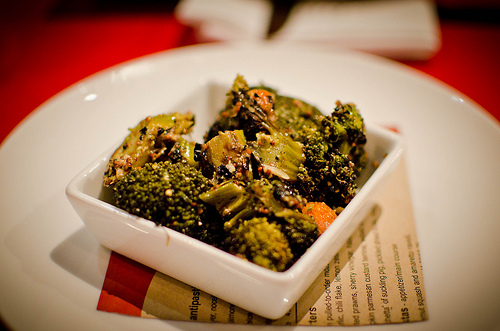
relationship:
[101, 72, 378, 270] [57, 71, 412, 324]
veggie in bowl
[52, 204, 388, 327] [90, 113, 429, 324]
bowl shadow on the paper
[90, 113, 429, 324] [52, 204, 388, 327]
paper under bowl shadow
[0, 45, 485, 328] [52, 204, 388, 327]
plate under bowl shadow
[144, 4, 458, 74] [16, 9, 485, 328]
white towel is on table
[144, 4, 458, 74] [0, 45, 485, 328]
white towel near plate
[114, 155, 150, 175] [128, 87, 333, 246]
spices on vegetables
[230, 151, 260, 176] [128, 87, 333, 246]
spices on vegetables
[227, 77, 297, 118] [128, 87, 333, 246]
spices on vegetables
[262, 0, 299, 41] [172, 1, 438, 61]
knife on towel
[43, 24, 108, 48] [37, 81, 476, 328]
table cloth underneath plate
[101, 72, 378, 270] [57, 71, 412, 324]
veggie in a bowl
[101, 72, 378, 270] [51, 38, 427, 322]
veggie in a bowl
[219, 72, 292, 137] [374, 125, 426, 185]
veggie in a bowl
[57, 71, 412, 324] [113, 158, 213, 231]
bowl full of broccoli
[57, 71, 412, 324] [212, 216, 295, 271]
bowl full of broccoli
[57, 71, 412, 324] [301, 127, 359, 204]
bowl full of broccoli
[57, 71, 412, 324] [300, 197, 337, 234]
bowl full of carrot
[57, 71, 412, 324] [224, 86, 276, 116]
bowl full of carrot